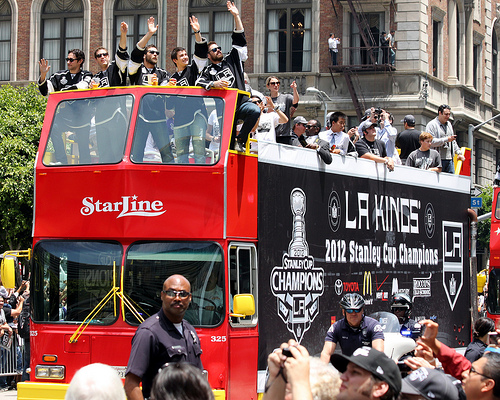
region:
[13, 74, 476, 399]
a red double decker bus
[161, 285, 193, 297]
dark black sunglasses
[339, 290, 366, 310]
a black helmet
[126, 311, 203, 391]
a black short sleeve uniform shirt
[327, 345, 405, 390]
a black and white baseball cap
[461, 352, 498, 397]
the head of a man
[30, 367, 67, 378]
the headlight of a bus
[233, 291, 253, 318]
a yellow side mirror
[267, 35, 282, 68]
part of a white curtain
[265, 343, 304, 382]
part of a black camera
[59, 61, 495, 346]
RED AND BLACK DOUBLE DECKER BUS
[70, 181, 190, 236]
WHITE STARLINE LOGO ON BUS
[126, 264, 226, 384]
BALD MAN STARING AT CAMERA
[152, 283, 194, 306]
EYE GLASSES ON MAN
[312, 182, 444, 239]
BLACK SIGN WITH LA KINGS IN WHITE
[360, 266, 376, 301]
YELLOW DOUBLE ARCHES LOGO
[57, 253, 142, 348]
YELLOW WINDSHIELD WIPER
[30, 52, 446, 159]
LA KINGS HOCKEY TEAM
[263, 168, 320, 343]
STANLEY CUP LOGO ON SIDE OF BUS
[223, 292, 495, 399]
CROWD OF SPECTATORS WATCHING TEAM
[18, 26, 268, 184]
people on a bus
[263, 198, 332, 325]
picture of a cup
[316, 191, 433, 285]
words on the bus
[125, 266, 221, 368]
officer looking around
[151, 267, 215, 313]
glasses on the officer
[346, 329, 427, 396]
hat on the man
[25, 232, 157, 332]
window on the bus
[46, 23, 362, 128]
hockey players on top of bus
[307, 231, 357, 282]
the year 2012 on bus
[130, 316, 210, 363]
uniform on the officer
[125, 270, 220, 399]
a policeman is watching the crowd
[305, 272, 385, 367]
a policeman is riding his bicycle .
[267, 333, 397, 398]
a person in the crowd is taking pictures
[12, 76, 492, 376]
a red double Decker bus.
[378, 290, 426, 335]
a policeman riding his motorcycle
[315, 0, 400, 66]
two people are standing in a balcony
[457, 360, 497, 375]
a person is wearing glasses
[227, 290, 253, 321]
a yellow rear view mirror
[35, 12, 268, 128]
hockey players are waving to the crowd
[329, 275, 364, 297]
a Toyota advertisement sign on a double Decker bus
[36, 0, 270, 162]
hockey players waving from bus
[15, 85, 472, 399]
red and yellow double decker bus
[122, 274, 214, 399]
standing officer watching crowd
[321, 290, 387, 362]
bike mounted officer in a helmet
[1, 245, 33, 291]
yellow side mirror on bus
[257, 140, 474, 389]
banner for LA Kings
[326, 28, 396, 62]
people on fire escape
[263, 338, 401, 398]
guy in black hat taking photo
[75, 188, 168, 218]
starline logo on bus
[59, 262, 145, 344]
yellow windshield wipers on bus